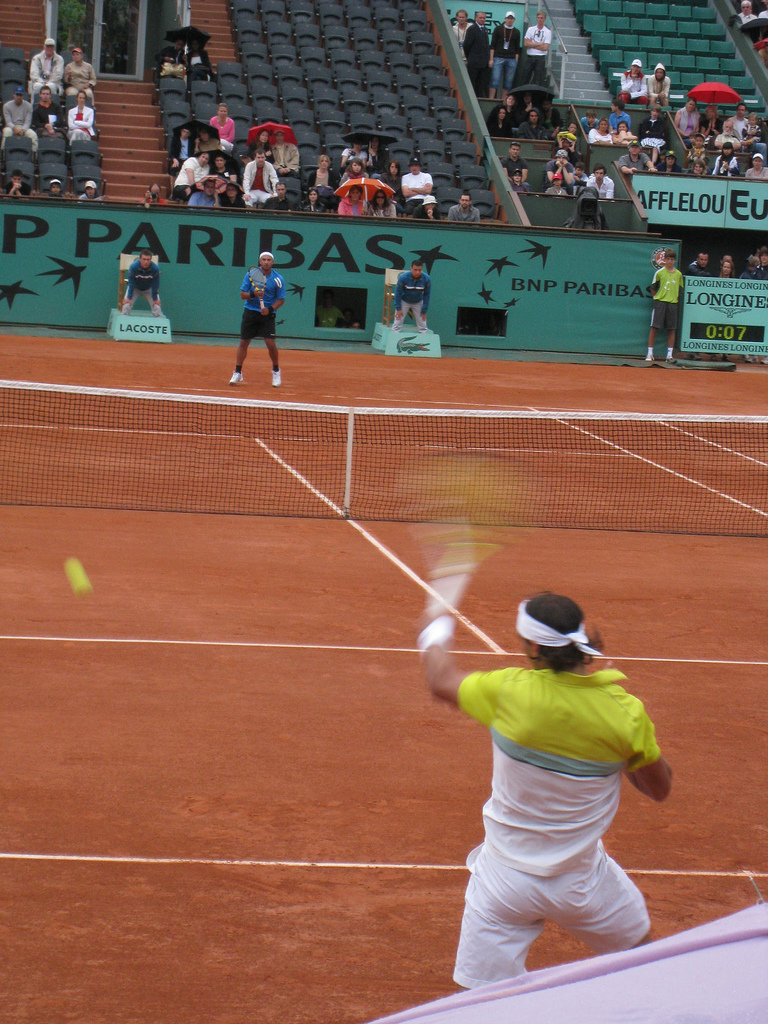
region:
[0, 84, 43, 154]
person sitting watching tennis match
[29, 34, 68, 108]
person sitting watching tennis match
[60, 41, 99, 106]
person sitting watching tennis match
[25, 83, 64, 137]
person sitting watching tennis match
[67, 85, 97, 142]
person sitting watching tennis match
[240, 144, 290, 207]
person sitting watching tennis match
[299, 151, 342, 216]
person sitting watching tennis match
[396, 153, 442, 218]
person sitting watching tennis match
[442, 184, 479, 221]
person sitting watching tennis match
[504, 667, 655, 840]
Person in yellow and white shirt on tennis court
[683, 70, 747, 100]
red umbrella on right in stands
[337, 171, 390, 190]
red and white umbrella in stands behind player in blue shirt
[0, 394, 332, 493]
tennis net separating the players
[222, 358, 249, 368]
black socks on player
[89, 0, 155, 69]
glass door above stairs in stands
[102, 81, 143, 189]
red stairs in stand leading up to glass door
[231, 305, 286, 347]
player in black shorts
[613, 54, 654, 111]
person watching tennis match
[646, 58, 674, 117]
person watching tennis match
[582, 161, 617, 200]
person watching tennis match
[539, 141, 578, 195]
person watching tennis match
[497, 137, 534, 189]
person watching tennis match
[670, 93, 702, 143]
person watching tennis match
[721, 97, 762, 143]
person watching tennis match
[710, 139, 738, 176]
person watching tennis match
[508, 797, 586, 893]
A person eating a orange.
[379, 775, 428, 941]
A person eating a orange.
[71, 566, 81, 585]
A tennis ball flying through the air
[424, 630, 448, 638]
Hand with a white wrist band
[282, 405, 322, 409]
The white edge of the tennis net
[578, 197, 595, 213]
A covered camera in the stands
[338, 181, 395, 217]
Two spectators under an umbrella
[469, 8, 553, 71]
Three people standing in the stands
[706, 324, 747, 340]
A digital timer with yellow numbers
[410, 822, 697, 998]
white shorts on player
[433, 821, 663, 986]
white shorts on player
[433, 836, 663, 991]
white shorts on player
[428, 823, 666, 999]
white shorts on player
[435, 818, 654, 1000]
white shorts on player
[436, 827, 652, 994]
white shorts on player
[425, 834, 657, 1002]
white shorts on player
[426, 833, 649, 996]
white shorts on player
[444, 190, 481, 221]
spectator watching tennis from the stands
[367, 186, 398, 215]
spectator watching tennis from the stands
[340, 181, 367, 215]
spectator watching tennis from the stands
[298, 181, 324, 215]
spectator watching tennis from the stands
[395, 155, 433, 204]
spectator watching tennis from the stands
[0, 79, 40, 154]
spectator watching tennis from the stands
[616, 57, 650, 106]
spectator watching tennis from the stands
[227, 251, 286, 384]
a tennis player on court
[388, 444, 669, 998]
a tennis player swinging racket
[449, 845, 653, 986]
a pair of white shorts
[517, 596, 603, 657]
a white bandana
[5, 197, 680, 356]
a blue stadium advertisement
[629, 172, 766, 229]
a blue stadium advertisement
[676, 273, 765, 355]
a blue stadium advertisement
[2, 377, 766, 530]
a long stretched tennis net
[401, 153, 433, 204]
A person is sitting down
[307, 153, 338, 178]
A person is sitting down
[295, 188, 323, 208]
A person is sitting down